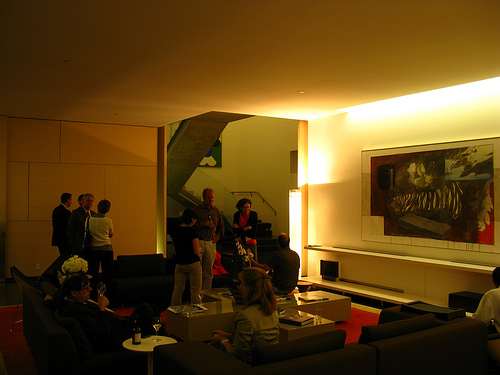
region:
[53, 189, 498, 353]
people in the room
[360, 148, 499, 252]
picture on the wall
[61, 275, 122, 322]
man is sitting down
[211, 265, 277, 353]
a woman is sitting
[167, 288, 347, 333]
the table is short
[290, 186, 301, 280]
the light is cylindrical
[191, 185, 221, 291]
a man is standing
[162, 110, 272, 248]
staircase to upper floor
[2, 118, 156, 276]
panels on the wall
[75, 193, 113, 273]
two people are talking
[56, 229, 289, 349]
People sitting on the chair.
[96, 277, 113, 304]
The man is holding on a glass.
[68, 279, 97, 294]
Person is wearing eyeglasses.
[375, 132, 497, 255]
A picture on the wll.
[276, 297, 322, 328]
A book on the table.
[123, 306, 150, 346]
A bottle on the table.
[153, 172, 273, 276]
The people are standing around talking.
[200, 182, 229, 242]
The man is holding a bottle.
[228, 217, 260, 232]
The lady arms are folded.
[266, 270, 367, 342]
The table is white.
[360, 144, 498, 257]
The picture on the wall.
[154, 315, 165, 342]
The wine glass on the table.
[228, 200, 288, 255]
The stairs in the next room.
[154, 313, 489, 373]
The sofa the woman is sitting on.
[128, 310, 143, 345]
The bottle of wine on the small circle table.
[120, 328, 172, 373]
The small circle table.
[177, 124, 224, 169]
The picture hanging on the wall in the next room.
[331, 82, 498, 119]
The light above the large frame on the wall.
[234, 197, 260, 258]
The lady in the red shirt and black sweater.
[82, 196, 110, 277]
woman carrying a black purse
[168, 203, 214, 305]
woman wearing a black shirt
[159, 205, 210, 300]
woman wearing tan pants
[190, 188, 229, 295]
man holding a beer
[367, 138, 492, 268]
beautiful artwork on the wall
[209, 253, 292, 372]
woman sitting on the sofa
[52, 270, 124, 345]
man sitting on the sofa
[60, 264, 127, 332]
man holding a glass of red wine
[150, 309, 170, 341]
glass of white wine on the table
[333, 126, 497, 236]
image on the wall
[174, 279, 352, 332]
table in the center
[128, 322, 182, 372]
stand between the couches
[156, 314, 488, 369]
couch in the room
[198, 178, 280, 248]
stairs in the back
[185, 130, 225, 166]
image on the wall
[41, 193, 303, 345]
people at a gathering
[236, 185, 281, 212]
rail on the stairs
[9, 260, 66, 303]
chair in the room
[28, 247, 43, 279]
outlet on the wall